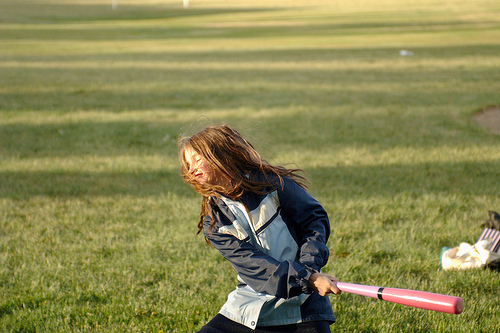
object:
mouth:
[190, 171, 204, 186]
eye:
[192, 156, 203, 166]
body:
[192, 169, 341, 332]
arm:
[268, 172, 331, 270]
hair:
[174, 113, 312, 251]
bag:
[470, 211, 499, 254]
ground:
[0, 0, 499, 332]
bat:
[332, 280, 464, 316]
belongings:
[440, 241, 486, 274]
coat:
[201, 168, 336, 330]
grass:
[10, 176, 142, 321]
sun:
[26, 194, 66, 222]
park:
[0, 0, 499, 332]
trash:
[396, 51, 411, 60]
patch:
[0, 288, 113, 327]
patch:
[130, 307, 181, 333]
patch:
[130, 280, 176, 318]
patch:
[58, 197, 115, 220]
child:
[178, 116, 341, 333]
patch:
[396, 48, 413, 57]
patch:
[103, 41, 163, 81]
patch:
[156, 22, 242, 70]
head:
[177, 124, 252, 185]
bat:
[307, 257, 465, 321]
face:
[180, 142, 216, 186]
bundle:
[454, 240, 478, 258]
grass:
[0, 0, 499, 332]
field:
[0, 0, 499, 332]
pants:
[196, 317, 332, 332]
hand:
[308, 271, 342, 296]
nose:
[185, 164, 195, 176]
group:
[440, 210, 499, 274]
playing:
[168, 112, 464, 333]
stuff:
[440, 240, 490, 274]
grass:
[325, 151, 496, 326]